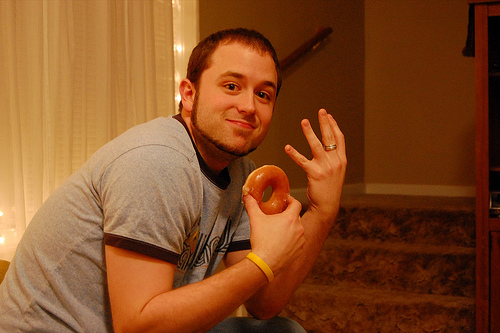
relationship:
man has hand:
[1, 28, 347, 332] [243, 190, 307, 274]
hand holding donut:
[243, 190, 307, 274] [241, 164, 290, 212]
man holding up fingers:
[1, 28, 347, 332] [280, 107, 346, 173]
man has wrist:
[1, 28, 347, 332] [249, 251, 276, 287]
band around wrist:
[246, 251, 276, 284] [249, 251, 276, 287]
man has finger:
[1, 28, 347, 332] [318, 108, 337, 157]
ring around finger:
[324, 143, 336, 153] [318, 108, 337, 157]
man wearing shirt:
[1, 28, 347, 332] [0, 114, 256, 332]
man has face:
[1, 28, 347, 332] [209, 46, 275, 150]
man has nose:
[1, 28, 347, 332] [238, 88, 257, 118]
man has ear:
[1, 28, 347, 332] [177, 78, 197, 113]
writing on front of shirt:
[177, 216, 233, 270] [0, 114, 256, 332]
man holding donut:
[1, 28, 347, 332] [241, 164, 290, 212]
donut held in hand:
[241, 164, 290, 212] [243, 190, 307, 274]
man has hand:
[1, 28, 347, 332] [286, 108, 347, 213]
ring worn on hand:
[324, 143, 336, 153] [286, 108, 347, 213]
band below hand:
[246, 251, 276, 284] [243, 190, 307, 274]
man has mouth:
[1, 28, 347, 332] [225, 118, 256, 131]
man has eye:
[1, 28, 347, 332] [223, 82, 239, 93]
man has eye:
[1, 28, 347, 332] [257, 90, 269, 101]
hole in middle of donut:
[259, 183, 276, 205] [241, 164, 290, 212]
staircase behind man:
[249, 189, 475, 332] [1, 28, 347, 332]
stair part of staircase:
[247, 283, 476, 332] [249, 189, 475, 332]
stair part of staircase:
[301, 236, 476, 295] [249, 189, 475, 332]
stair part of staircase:
[296, 193, 475, 246] [249, 189, 475, 332]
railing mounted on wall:
[273, 24, 332, 69] [198, 0, 362, 201]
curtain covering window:
[0, 0, 175, 264] [0, 0, 198, 117]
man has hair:
[1, 28, 347, 332] [177, 27, 282, 111]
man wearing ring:
[1, 28, 347, 332] [324, 143, 336, 153]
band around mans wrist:
[246, 251, 276, 284] [249, 251, 276, 287]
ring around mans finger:
[324, 143, 336, 153] [318, 108, 337, 157]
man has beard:
[1, 28, 347, 332] [189, 88, 258, 158]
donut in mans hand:
[241, 164, 290, 212] [243, 190, 307, 274]